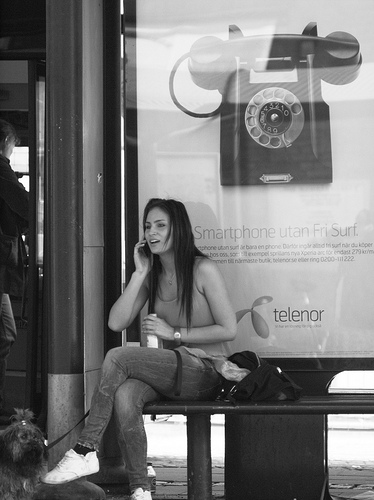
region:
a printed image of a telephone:
[164, 19, 365, 195]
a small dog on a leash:
[2, 405, 88, 498]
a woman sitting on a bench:
[41, 191, 240, 498]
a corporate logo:
[229, 293, 326, 341]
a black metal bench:
[131, 385, 373, 499]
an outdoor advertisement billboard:
[134, 0, 372, 357]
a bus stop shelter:
[44, 1, 371, 497]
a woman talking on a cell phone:
[38, 191, 235, 499]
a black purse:
[203, 345, 301, 405]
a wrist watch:
[169, 323, 183, 344]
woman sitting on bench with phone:
[41, 182, 250, 498]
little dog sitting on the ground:
[0, 400, 52, 497]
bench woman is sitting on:
[141, 388, 372, 498]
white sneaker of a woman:
[40, 446, 106, 487]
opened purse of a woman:
[210, 338, 304, 412]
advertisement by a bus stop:
[157, 5, 368, 360]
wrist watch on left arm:
[163, 322, 189, 345]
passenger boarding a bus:
[0, 148, 43, 412]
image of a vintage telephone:
[161, 11, 369, 191]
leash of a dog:
[38, 402, 98, 450]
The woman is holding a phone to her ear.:
[128, 200, 193, 260]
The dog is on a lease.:
[1, 335, 204, 497]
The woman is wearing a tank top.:
[128, 253, 231, 356]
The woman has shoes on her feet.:
[37, 443, 158, 498]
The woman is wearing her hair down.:
[119, 180, 216, 332]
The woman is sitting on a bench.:
[79, 196, 372, 496]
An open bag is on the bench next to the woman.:
[212, 346, 307, 404]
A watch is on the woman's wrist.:
[169, 320, 185, 350]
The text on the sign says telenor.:
[251, 291, 340, 335]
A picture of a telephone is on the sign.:
[182, 1, 367, 201]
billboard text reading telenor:
[271, 305, 329, 323]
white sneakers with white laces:
[42, 452, 100, 484]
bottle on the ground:
[148, 458, 159, 499]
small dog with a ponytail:
[1, 397, 48, 498]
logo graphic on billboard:
[235, 292, 275, 342]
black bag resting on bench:
[219, 348, 301, 409]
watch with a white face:
[173, 326, 181, 344]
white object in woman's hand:
[141, 312, 159, 346]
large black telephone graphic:
[163, 13, 365, 189]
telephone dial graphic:
[244, 84, 303, 150]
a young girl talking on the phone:
[35, 182, 249, 495]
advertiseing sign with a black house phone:
[123, 0, 370, 380]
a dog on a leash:
[3, 338, 218, 495]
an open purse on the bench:
[201, 331, 309, 412]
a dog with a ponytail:
[8, 399, 55, 481]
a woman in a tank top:
[100, 192, 244, 354]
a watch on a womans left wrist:
[144, 310, 195, 346]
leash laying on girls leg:
[67, 325, 200, 399]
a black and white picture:
[5, 6, 372, 497]